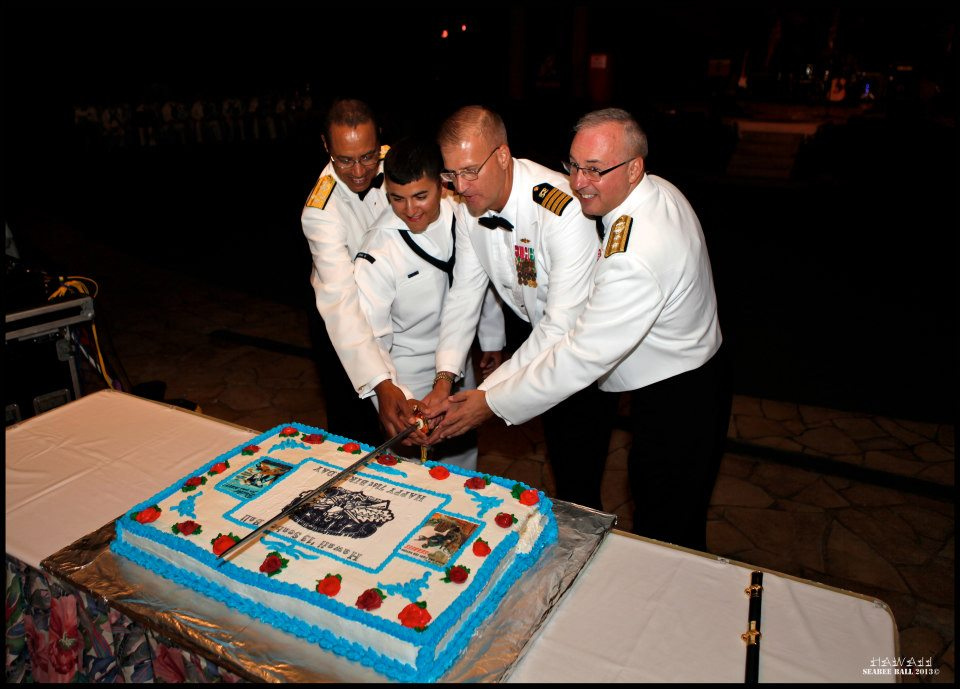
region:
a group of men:
[286, 88, 741, 562]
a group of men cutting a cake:
[96, 84, 736, 679]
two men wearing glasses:
[415, 98, 737, 590]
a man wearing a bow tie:
[412, 97, 616, 516]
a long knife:
[208, 412, 476, 580]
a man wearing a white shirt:
[292, 92, 420, 449]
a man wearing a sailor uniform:
[344, 120, 514, 471]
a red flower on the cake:
[393, 599, 434, 638]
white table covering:
[0, 374, 912, 681]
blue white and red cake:
[96, 401, 576, 679]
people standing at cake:
[260, 118, 803, 523]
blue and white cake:
[139, 425, 421, 685]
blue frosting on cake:
[87, 428, 588, 683]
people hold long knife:
[161, 381, 484, 614]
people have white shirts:
[351, 156, 674, 389]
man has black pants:
[622, 389, 756, 542]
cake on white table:
[19, 381, 603, 649]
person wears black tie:
[411, 239, 465, 335]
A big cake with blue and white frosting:
[102, 407, 566, 682]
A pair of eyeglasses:
[548, 135, 644, 185]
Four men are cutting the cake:
[105, 64, 742, 681]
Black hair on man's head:
[367, 126, 452, 241]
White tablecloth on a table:
[1, 374, 907, 681]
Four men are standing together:
[278, 76, 755, 557]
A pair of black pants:
[611, 333, 744, 556]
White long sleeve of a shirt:
[481, 252, 666, 431]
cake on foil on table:
[104, 402, 563, 680]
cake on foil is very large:
[100, 412, 564, 686]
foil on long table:
[29, 420, 615, 684]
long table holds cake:
[7, 382, 910, 686]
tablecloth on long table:
[4, 383, 909, 686]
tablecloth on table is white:
[7, 382, 909, 683]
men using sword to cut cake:
[207, 405, 456, 581]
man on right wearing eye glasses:
[554, 147, 641, 195]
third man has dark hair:
[376, 135, 441, 204]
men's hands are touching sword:
[365, 360, 496, 458]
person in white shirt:
[304, 110, 389, 391]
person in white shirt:
[353, 157, 498, 427]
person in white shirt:
[433, 116, 592, 410]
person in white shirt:
[490, 117, 723, 429]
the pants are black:
[617, 351, 721, 548]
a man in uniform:
[548, 86, 873, 522]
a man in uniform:
[453, 70, 606, 392]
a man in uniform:
[381, 174, 537, 460]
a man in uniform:
[308, 30, 469, 311]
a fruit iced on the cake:
[405, 614, 432, 644]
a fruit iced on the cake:
[352, 560, 372, 613]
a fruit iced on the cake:
[239, 557, 284, 605]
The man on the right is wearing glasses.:
[560, 108, 649, 219]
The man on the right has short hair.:
[565, 111, 654, 220]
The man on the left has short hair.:
[315, 102, 389, 200]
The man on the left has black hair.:
[314, 94, 392, 200]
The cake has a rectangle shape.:
[108, 418, 561, 686]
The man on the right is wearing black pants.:
[540, 105, 730, 554]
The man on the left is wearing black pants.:
[298, 94, 398, 447]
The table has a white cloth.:
[4, 372, 906, 686]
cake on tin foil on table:
[32, 408, 631, 682]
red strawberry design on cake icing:
[387, 594, 444, 635]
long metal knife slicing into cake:
[203, 408, 437, 586]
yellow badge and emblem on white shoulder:
[595, 204, 638, 269]